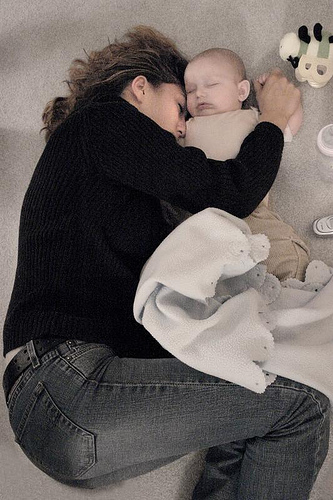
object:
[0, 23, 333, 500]
mom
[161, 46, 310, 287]
baby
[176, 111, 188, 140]
nose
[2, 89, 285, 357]
sweater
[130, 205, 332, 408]
blanket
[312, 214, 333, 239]
shoe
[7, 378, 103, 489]
pocket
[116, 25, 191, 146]
head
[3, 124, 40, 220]
shadow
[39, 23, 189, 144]
hair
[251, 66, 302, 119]
hand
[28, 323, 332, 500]
leg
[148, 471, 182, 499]
floor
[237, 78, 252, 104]
ear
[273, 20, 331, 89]
toy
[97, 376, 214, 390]
stitching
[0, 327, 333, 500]
jeans